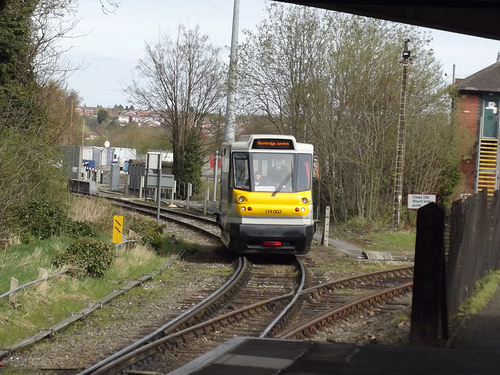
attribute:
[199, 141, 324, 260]
train — yellow, white, small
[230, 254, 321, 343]
tracks — intersecting, curved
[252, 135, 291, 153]
lettering — orange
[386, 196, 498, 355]
fence — wooden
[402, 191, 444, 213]
sign — white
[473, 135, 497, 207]
stairs — yellow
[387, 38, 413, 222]
utility pole — tall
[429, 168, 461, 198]
bush — leafy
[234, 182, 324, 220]
front — yellow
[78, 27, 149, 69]
sky — blue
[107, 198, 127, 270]
sign — yellow